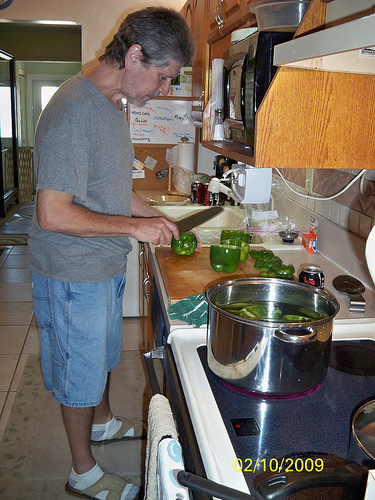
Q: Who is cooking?
A: Man.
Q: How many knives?
A: 1.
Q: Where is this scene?
A: Kitchen.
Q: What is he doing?
A: Cooking.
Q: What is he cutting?
A: Pepper.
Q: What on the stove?
A: Pot.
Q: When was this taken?
A: 02/10/2009.